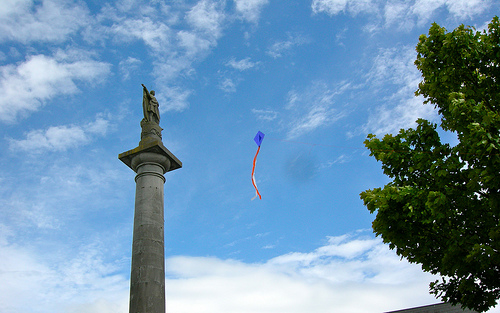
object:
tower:
[118, 84, 184, 309]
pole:
[117, 83, 185, 312]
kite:
[249, 125, 265, 201]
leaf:
[377, 192, 419, 210]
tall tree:
[359, 14, 500, 310]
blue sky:
[287, 136, 337, 180]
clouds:
[2, 2, 498, 307]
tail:
[251, 146, 262, 201]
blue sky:
[187, 197, 247, 226]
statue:
[140, 83, 165, 140]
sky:
[0, 0, 499, 310]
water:
[139, 83, 164, 144]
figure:
[118, 83, 183, 171]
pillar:
[132, 158, 165, 313]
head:
[149, 90, 155, 96]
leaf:
[390, 146, 432, 173]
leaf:
[374, 148, 384, 158]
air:
[190, 47, 333, 300]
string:
[250, 148, 262, 201]